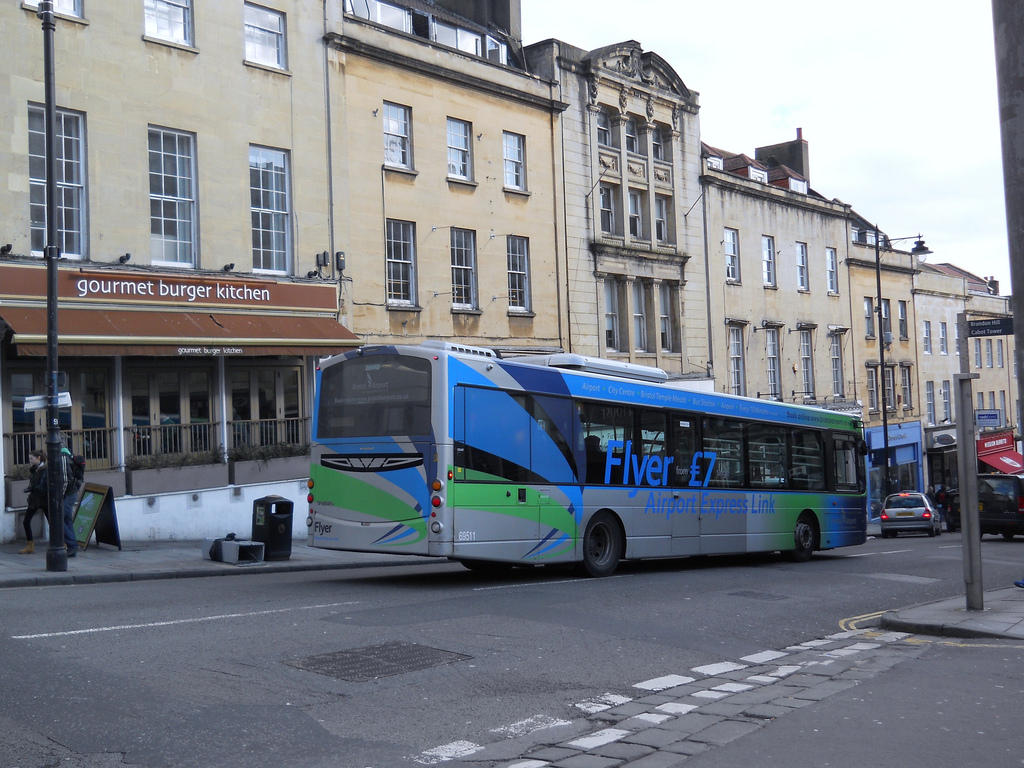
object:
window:
[381, 217, 417, 312]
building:
[321, 0, 570, 354]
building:
[701, 124, 928, 534]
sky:
[517, 0, 1013, 298]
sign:
[76, 279, 271, 301]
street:
[0, 526, 1024, 768]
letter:
[79, 279, 88, 297]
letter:
[147, 280, 156, 295]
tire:
[584, 515, 622, 578]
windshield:
[703, 414, 864, 493]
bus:
[307, 338, 869, 578]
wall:
[291, 45, 390, 352]